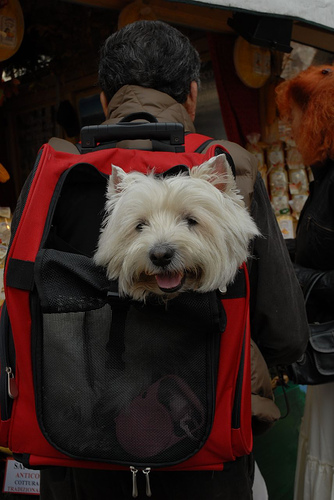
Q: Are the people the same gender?
A: No, they are both male and female.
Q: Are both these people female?
A: No, they are both male and female.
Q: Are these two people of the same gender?
A: No, they are both male and female.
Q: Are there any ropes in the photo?
A: No, there are no ropes.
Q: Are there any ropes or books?
A: No, there are no ropes or books.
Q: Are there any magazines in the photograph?
A: No, there are no magazines.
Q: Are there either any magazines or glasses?
A: No, there are no magazines or glasses.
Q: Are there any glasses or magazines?
A: No, there are no magazines or glasses.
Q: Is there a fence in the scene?
A: No, there are no fences.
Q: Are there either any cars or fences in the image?
A: No, there are no fences or cars.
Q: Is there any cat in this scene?
A: No, there are no cats.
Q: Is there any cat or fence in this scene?
A: No, there are no cats or fences.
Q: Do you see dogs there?
A: Yes, there is a dog.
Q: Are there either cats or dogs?
A: Yes, there is a dog.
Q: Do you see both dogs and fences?
A: No, there is a dog but no fences.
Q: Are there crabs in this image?
A: No, there are no crabs.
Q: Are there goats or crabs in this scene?
A: No, there are no crabs or goats.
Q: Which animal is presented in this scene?
A: The animal is a dog.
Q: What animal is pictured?
A: The animal is a dog.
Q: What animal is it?
A: The animal is a dog.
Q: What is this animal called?
A: This is a dog.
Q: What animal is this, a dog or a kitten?
A: This is a dog.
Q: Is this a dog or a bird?
A: This is a dog.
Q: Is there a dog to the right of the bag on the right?
A: No, the dog is to the left of the bag.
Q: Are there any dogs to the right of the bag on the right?
A: No, the dog is to the left of the bag.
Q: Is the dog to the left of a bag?
A: Yes, the dog is to the left of a bag.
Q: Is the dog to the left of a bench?
A: No, the dog is to the left of a bag.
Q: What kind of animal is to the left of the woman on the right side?
A: The animal is a dog.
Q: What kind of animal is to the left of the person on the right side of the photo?
A: The animal is a dog.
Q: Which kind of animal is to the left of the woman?
A: The animal is a dog.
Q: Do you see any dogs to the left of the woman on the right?
A: Yes, there is a dog to the left of the woman.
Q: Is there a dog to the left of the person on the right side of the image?
A: Yes, there is a dog to the left of the woman.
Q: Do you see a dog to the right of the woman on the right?
A: No, the dog is to the left of the woman.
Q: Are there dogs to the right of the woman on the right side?
A: No, the dog is to the left of the woman.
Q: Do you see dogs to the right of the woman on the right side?
A: No, the dog is to the left of the woman.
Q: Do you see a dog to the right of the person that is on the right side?
A: No, the dog is to the left of the woman.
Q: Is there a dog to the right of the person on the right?
A: No, the dog is to the left of the woman.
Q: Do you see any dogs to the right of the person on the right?
A: No, the dog is to the left of the woman.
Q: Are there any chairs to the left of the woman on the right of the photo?
A: No, there is a dog to the left of the woman.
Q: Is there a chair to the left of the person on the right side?
A: No, there is a dog to the left of the woman.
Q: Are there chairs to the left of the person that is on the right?
A: No, there is a dog to the left of the woman.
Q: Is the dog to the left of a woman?
A: Yes, the dog is to the left of a woman.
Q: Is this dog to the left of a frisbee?
A: No, the dog is to the left of a woman.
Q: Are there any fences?
A: No, there are no fences.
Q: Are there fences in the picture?
A: No, there are no fences.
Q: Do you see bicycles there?
A: No, there are no bicycles.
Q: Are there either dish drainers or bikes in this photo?
A: No, there are no bikes or dish drainers.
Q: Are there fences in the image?
A: No, there are no fences.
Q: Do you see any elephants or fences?
A: No, there are no fences or elephants.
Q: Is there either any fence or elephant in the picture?
A: No, there are no fences or elephants.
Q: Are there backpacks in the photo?
A: Yes, there is a backpack.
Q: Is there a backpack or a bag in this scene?
A: Yes, there is a backpack.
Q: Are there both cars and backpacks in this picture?
A: No, there is a backpack but no cars.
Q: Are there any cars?
A: No, there are no cars.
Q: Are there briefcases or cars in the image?
A: No, there are no cars or briefcases.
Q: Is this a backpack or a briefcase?
A: This is a backpack.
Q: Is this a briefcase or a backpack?
A: This is a backpack.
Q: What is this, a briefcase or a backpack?
A: This is a backpack.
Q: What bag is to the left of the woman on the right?
A: The bag is a backpack.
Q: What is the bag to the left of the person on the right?
A: The bag is a backpack.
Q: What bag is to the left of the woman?
A: The bag is a backpack.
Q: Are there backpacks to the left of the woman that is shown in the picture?
A: Yes, there is a backpack to the left of the woman.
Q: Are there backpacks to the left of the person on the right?
A: Yes, there is a backpack to the left of the woman.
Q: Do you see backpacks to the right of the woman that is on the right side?
A: No, the backpack is to the left of the woman.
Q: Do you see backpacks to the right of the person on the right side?
A: No, the backpack is to the left of the woman.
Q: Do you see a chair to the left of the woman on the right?
A: No, there is a backpack to the left of the woman.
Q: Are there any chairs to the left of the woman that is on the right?
A: No, there is a backpack to the left of the woman.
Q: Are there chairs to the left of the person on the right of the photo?
A: No, there is a backpack to the left of the woman.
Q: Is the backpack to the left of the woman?
A: Yes, the backpack is to the left of the woman.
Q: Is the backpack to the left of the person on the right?
A: Yes, the backpack is to the left of the woman.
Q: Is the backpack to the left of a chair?
A: No, the backpack is to the left of the woman.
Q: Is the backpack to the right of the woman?
A: No, the backpack is to the left of the woman.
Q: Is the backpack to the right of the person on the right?
A: No, the backpack is to the left of the woman.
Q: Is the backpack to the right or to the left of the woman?
A: The backpack is to the left of the woman.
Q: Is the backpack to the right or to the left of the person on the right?
A: The backpack is to the left of the woman.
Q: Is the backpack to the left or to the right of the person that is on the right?
A: The backpack is to the left of the woman.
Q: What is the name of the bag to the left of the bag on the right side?
A: The bag is a backpack.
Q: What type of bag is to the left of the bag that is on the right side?
A: The bag is a backpack.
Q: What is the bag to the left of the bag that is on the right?
A: The bag is a backpack.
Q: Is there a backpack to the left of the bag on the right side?
A: Yes, there is a backpack to the left of the bag.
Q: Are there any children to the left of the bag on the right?
A: No, there is a backpack to the left of the bag.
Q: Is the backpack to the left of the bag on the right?
A: Yes, the backpack is to the left of the bag.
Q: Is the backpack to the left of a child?
A: No, the backpack is to the left of the bag.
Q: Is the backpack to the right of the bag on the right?
A: No, the backpack is to the left of the bag.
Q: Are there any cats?
A: No, there are no cats.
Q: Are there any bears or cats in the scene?
A: No, there are no cats or bears.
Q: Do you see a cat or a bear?
A: No, there are no cats or bears.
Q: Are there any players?
A: No, there are no players.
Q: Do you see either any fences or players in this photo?
A: No, there are no players or fences.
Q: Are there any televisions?
A: Yes, there is a television.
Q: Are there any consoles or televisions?
A: Yes, there is a television.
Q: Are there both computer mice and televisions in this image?
A: No, there is a television but no computer mice.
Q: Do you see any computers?
A: No, there are no computers.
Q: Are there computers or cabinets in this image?
A: No, there are no computers or cabinets.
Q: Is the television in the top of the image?
A: Yes, the television is in the top of the image.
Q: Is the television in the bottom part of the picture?
A: No, the television is in the top of the image.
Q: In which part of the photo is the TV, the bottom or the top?
A: The TV is in the top of the image.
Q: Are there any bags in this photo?
A: Yes, there is a bag.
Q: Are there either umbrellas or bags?
A: Yes, there is a bag.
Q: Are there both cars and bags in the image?
A: No, there is a bag but no cars.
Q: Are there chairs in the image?
A: No, there are no chairs.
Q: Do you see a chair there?
A: No, there are no chairs.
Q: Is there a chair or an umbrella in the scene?
A: No, there are no chairs or umbrellas.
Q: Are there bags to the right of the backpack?
A: Yes, there is a bag to the right of the backpack.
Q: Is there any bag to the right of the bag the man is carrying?
A: Yes, there is a bag to the right of the backpack.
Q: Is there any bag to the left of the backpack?
A: No, the bag is to the right of the backpack.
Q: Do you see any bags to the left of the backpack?
A: No, the bag is to the right of the backpack.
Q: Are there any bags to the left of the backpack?
A: No, the bag is to the right of the backpack.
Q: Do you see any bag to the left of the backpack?
A: No, the bag is to the right of the backpack.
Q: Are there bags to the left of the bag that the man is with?
A: No, the bag is to the right of the backpack.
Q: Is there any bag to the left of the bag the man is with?
A: No, the bag is to the right of the backpack.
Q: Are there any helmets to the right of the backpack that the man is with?
A: No, there is a bag to the right of the backpack.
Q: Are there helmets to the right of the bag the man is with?
A: No, there is a bag to the right of the backpack.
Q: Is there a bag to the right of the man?
A: Yes, there is a bag to the right of the man.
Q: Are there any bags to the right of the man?
A: Yes, there is a bag to the right of the man.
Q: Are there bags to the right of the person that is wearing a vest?
A: Yes, there is a bag to the right of the man.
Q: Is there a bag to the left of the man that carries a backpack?
A: No, the bag is to the right of the man.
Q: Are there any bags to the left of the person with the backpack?
A: No, the bag is to the right of the man.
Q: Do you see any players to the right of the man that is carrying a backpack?
A: No, there is a bag to the right of the man.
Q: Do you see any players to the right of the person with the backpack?
A: No, there is a bag to the right of the man.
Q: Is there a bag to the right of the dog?
A: Yes, there is a bag to the right of the dog.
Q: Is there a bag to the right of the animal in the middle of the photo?
A: Yes, there is a bag to the right of the dog.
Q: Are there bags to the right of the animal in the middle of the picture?
A: Yes, there is a bag to the right of the dog.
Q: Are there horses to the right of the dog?
A: No, there is a bag to the right of the dog.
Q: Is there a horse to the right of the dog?
A: No, there is a bag to the right of the dog.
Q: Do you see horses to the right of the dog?
A: No, there is a bag to the right of the dog.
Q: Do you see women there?
A: Yes, there is a woman.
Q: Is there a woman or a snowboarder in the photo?
A: Yes, there is a woman.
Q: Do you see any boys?
A: No, there are no boys.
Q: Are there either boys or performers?
A: No, there are no boys or performers.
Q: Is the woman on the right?
A: Yes, the woman is on the right of the image.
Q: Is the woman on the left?
A: No, the woman is on the right of the image.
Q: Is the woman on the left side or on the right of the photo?
A: The woman is on the right of the image.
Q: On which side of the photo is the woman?
A: The woman is on the right of the image.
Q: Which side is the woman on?
A: The woman is on the right of the image.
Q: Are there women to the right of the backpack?
A: Yes, there is a woman to the right of the backpack.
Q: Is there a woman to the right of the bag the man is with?
A: Yes, there is a woman to the right of the backpack.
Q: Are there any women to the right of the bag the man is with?
A: Yes, there is a woman to the right of the backpack.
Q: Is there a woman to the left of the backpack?
A: No, the woman is to the right of the backpack.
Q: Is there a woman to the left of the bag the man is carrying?
A: No, the woman is to the right of the backpack.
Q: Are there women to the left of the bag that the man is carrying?
A: No, the woman is to the right of the backpack.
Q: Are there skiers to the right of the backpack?
A: No, there is a woman to the right of the backpack.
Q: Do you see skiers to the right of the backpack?
A: No, there is a woman to the right of the backpack.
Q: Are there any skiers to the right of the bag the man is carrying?
A: No, there is a woman to the right of the backpack.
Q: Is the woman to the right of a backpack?
A: Yes, the woman is to the right of a backpack.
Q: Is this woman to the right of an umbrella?
A: No, the woman is to the right of a backpack.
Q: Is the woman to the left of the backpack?
A: No, the woman is to the right of the backpack.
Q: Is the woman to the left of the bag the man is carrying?
A: No, the woman is to the right of the backpack.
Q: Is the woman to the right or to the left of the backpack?
A: The woman is to the right of the backpack.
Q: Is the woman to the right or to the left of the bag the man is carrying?
A: The woman is to the right of the backpack.